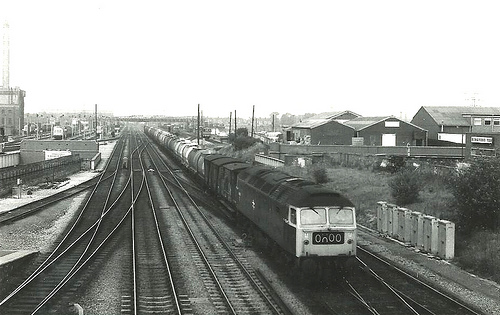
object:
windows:
[300, 209, 326, 225]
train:
[142, 122, 359, 286]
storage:
[289, 119, 356, 145]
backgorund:
[11, 6, 488, 137]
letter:
[336, 234, 342, 243]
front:
[294, 191, 356, 258]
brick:
[5, 108, 18, 122]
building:
[0, 90, 24, 140]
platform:
[0, 159, 98, 221]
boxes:
[377, 201, 388, 234]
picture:
[0, 0, 500, 315]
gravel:
[469, 293, 496, 314]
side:
[345, 85, 496, 300]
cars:
[204, 152, 256, 218]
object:
[437, 220, 456, 260]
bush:
[455, 154, 500, 233]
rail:
[95, 167, 233, 308]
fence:
[0, 154, 79, 191]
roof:
[423, 106, 499, 126]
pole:
[198, 103, 200, 145]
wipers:
[310, 207, 321, 217]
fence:
[283, 146, 464, 156]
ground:
[0, 172, 195, 286]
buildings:
[340, 116, 428, 148]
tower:
[0, 84, 25, 151]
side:
[7, 4, 84, 228]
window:
[290, 208, 297, 225]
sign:
[471, 137, 493, 144]